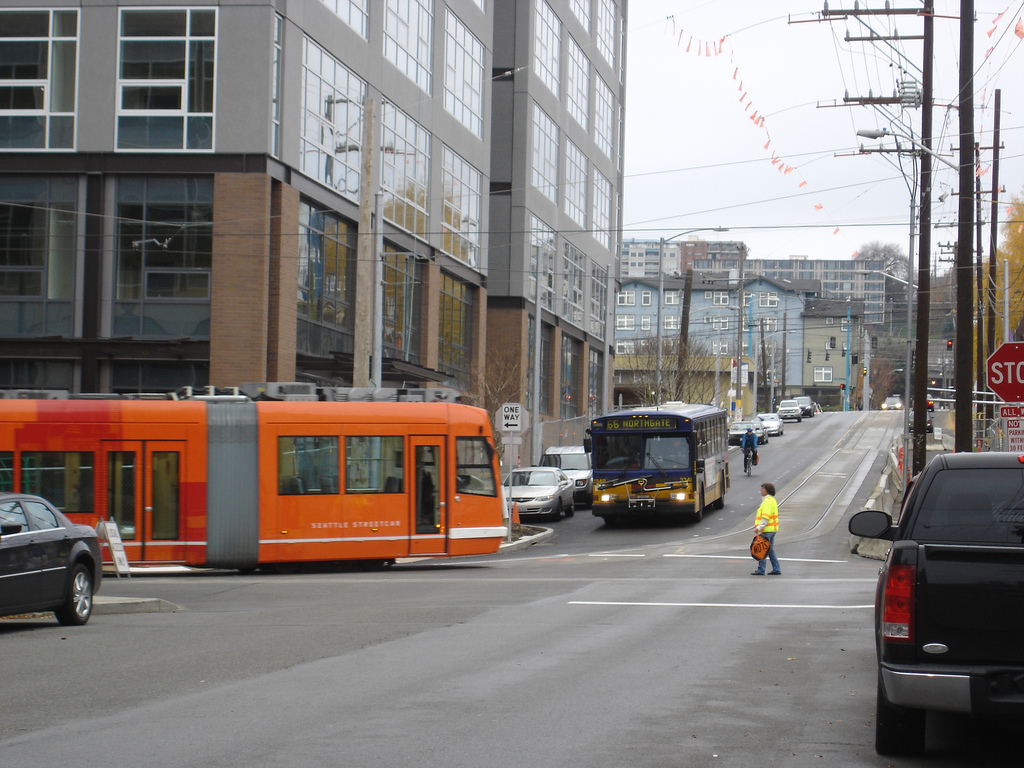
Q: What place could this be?
A: It is a road.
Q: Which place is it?
A: It is a road.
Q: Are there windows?
A: Yes, there is a window.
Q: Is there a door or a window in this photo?
A: Yes, there is a window.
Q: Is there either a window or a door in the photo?
A: Yes, there is a window.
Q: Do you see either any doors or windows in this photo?
A: Yes, there is a window.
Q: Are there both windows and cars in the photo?
A: Yes, there are both a window and a car.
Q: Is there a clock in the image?
A: No, there are no clocks.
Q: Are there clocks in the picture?
A: No, there are no clocks.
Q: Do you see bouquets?
A: No, there are no bouquets.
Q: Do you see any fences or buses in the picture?
A: Yes, there is a bus.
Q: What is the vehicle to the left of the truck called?
A: The vehicle is a bus.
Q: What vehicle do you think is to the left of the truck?
A: The vehicle is a bus.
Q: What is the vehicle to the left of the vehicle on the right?
A: The vehicle is a bus.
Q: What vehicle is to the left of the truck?
A: The vehicle is a bus.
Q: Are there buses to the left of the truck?
A: Yes, there is a bus to the left of the truck.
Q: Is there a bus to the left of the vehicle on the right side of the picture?
A: Yes, there is a bus to the left of the truck.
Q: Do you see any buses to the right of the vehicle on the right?
A: No, the bus is to the left of the truck.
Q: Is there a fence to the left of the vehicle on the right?
A: No, there is a bus to the left of the truck.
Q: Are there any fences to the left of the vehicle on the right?
A: No, there is a bus to the left of the truck.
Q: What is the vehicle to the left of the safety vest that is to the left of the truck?
A: The vehicle is a bus.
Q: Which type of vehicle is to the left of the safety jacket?
A: The vehicle is a bus.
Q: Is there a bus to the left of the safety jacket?
A: Yes, there is a bus to the left of the safety jacket.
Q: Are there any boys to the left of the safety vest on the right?
A: No, there is a bus to the left of the safety vest.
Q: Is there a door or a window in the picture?
A: Yes, there is a window.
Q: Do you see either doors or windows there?
A: Yes, there is a window.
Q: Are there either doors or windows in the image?
A: Yes, there is a window.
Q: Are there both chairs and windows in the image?
A: No, there is a window but no chairs.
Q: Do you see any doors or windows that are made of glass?
A: Yes, the window is made of glass.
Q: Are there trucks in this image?
A: Yes, there is a truck.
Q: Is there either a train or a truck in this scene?
A: Yes, there is a truck.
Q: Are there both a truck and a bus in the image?
A: Yes, there are both a truck and a bus.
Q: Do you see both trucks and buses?
A: Yes, there are both a truck and a bus.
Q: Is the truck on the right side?
A: Yes, the truck is on the right of the image.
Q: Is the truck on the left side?
A: No, the truck is on the right of the image.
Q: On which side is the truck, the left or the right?
A: The truck is on the right of the image.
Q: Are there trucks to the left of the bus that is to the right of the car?
A: No, the truck is to the right of the bus.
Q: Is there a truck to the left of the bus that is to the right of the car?
A: No, the truck is to the right of the bus.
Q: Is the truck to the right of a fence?
A: No, the truck is to the right of the bus.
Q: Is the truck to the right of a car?
A: Yes, the truck is to the right of a car.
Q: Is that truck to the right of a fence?
A: No, the truck is to the right of a car.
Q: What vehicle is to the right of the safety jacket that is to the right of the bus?
A: The vehicle is a truck.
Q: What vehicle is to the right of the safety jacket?
A: The vehicle is a truck.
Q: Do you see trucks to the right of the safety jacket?
A: Yes, there is a truck to the right of the safety jacket.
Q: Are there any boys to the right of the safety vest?
A: No, there is a truck to the right of the safety vest.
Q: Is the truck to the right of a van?
A: No, the truck is to the right of a safety jacket.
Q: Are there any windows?
A: Yes, there is a window.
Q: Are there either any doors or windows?
A: Yes, there is a window.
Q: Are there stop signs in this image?
A: Yes, there is a stop sign.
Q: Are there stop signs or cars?
A: Yes, there is a stop sign.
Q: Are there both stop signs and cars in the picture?
A: Yes, there are both a stop sign and a car.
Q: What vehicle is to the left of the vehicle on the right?
A: The vehicle is a car.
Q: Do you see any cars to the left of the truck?
A: Yes, there is a car to the left of the truck.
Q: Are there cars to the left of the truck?
A: Yes, there is a car to the left of the truck.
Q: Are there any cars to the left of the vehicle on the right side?
A: Yes, there is a car to the left of the truck.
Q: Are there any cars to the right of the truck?
A: No, the car is to the left of the truck.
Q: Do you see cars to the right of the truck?
A: No, the car is to the left of the truck.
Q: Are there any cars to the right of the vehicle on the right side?
A: No, the car is to the left of the truck.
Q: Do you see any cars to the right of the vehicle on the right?
A: No, the car is to the left of the truck.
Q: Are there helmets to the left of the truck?
A: No, there is a car to the left of the truck.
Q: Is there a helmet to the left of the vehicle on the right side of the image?
A: No, there is a car to the left of the truck.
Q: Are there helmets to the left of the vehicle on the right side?
A: No, there is a car to the left of the truck.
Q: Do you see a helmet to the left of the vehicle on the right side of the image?
A: No, there is a car to the left of the truck.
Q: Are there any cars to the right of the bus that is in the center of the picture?
A: No, the car is to the left of the bus.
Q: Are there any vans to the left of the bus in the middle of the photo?
A: No, there is a car to the left of the bus.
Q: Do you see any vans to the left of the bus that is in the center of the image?
A: No, there is a car to the left of the bus.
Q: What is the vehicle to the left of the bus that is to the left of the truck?
A: The vehicle is a car.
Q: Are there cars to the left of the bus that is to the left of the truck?
A: Yes, there is a car to the left of the bus.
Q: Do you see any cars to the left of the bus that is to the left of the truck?
A: Yes, there is a car to the left of the bus.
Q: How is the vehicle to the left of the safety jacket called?
A: The vehicle is a car.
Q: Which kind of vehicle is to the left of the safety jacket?
A: The vehicle is a car.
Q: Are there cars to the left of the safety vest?
A: Yes, there is a car to the left of the safety vest.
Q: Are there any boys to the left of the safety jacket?
A: No, there is a car to the left of the safety jacket.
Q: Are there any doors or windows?
A: Yes, there is a window.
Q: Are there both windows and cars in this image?
A: Yes, there are both a window and a car.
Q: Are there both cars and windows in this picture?
A: Yes, there are both a window and a car.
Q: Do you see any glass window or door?
A: Yes, there is a glass window.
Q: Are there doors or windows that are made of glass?
A: Yes, the window is made of glass.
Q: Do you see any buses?
A: Yes, there is a bus.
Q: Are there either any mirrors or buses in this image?
A: Yes, there is a bus.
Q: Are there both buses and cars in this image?
A: Yes, there are both a bus and a car.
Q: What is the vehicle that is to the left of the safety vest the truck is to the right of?
A: The vehicle is a bus.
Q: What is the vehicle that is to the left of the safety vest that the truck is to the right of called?
A: The vehicle is a bus.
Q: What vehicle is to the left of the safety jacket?
A: The vehicle is a bus.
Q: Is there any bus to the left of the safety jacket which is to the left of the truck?
A: Yes, there is a bus to the left of the safety vest.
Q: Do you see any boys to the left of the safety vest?
A: No, there is a bus to the left of the safety vest.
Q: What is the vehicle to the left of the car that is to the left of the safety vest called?
A: The vehicle is a bus.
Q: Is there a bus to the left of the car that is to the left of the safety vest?
A: Yes, there is a bus to the left of the car.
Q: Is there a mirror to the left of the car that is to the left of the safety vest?
A: No, there is a bus to the left of the car.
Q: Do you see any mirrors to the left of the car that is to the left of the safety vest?
A: No, there is a bus to the left of the car.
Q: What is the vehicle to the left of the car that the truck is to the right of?
A: The vehicle is a bus.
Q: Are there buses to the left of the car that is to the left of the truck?
A: Yes, there is a bus to the left of the car.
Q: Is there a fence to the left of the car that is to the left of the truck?
A: No, there is a bus to the left of the car.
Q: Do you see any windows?
A: Yes, there is a window.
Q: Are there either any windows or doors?
A: Yes, there is a window.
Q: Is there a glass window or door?
A: Yes, there is a glass window.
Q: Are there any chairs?
A: No, there are no chairs.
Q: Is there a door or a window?
A: Yes, there is a window.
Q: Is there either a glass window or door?
A: Yes, there is a glass window.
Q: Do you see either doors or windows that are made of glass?
A: Yes, the window is made of glass.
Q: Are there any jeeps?
A: No, there are no jeeps.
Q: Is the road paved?
A: Yes, the road is paved.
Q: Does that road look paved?
A: Yes, the road is paved.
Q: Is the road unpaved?
A: No, the road is paved.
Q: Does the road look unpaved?
A: No, the road is paved.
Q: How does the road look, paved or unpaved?
A: The road is paved.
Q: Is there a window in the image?
A: Yes, there is a window.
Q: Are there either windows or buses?
A: Yes, there is a window.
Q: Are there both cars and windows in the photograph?
A: Yes, there are both a window and a car.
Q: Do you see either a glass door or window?
A: Yes, there is a glass window.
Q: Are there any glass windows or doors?
A: Yes, there is a glass window.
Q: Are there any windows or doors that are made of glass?
A: Yes, the window is made of glass.